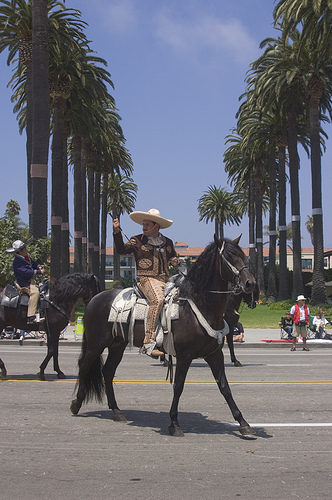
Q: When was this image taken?
A: Daytime.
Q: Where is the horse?
A: On a street.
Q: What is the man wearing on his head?
A: A sombrero.